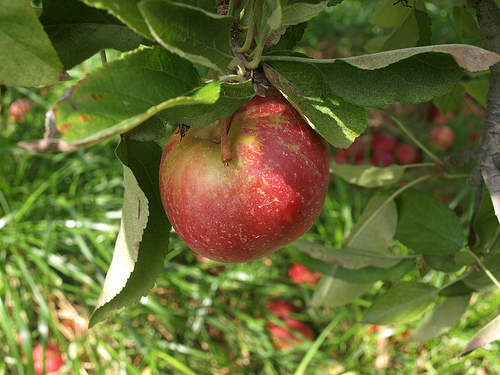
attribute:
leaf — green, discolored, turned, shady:
[33, 43, 252, 152]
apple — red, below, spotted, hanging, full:
[160, 91, 330, 265]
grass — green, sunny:
[3, 88, 497, 372]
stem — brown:
[220, 112, 234, 167]